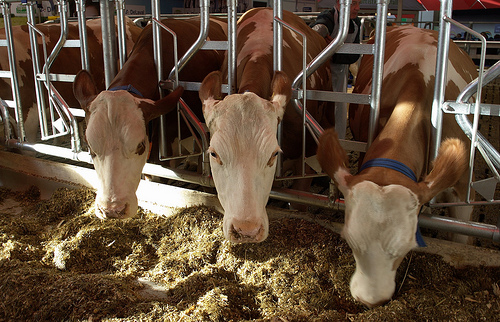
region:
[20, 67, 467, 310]
three cows grazing behind a fence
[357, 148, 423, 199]
blue collar of a cow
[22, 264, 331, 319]
hay and grass for cows to eat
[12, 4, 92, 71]
metal gate in front of cows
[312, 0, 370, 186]
farmer in the back of cows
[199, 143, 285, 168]
eyes of a cow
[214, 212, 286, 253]
nose and mouth of a cow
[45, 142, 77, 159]
sunlight shining on gate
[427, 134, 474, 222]
left ear of a cow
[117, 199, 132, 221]
nostril of a cow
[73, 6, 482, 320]
three cows grazing on grass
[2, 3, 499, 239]
metal fence barrier in cow pen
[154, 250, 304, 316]
green cut grass on floor before cow feeding pen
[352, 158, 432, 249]
blue cow collar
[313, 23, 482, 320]
brown and white cow feeding from cut green grass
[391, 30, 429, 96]
white spot on back of light brown cow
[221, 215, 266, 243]
two cow nostrils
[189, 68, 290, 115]
two cow ears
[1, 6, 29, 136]
metal fence spoke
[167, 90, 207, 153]
multi-colored cow tie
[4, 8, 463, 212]
4 cows are pictured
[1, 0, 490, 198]
the cows are brown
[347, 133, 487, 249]
the cow has a blue collar around its neck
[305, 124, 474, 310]
the cow is eating grass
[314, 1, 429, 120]
a man is behind the cows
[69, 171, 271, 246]
the cows have pink noses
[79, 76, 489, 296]
the cow's heads are white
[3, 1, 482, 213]
the cows are sticking heads through metal gates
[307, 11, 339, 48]
the man is wearing gloves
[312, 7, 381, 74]
the man is wearing a black shirt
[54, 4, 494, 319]
three cows feeding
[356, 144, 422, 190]
a blue collar on a cow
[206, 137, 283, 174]
a cow with brown around its eyes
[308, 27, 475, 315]
a brown and white cow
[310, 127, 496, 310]
a cow with its face in the ground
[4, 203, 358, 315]
brown animal feed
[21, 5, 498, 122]
silver metal fence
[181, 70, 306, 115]
the ears of a cow bent backwards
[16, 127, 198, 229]
bright white light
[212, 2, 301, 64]
a white patch on a cow's back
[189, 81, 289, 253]
cow with white face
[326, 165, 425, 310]
cow with white face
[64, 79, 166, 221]
cow with white face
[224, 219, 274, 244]
pink nose of cow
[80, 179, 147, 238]
pink nose of call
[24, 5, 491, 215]
metal bars around cows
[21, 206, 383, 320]
cows being fed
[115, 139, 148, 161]
brown eye of cow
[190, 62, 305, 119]
ears of cow are back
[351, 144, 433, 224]
blue collar around neck of cow